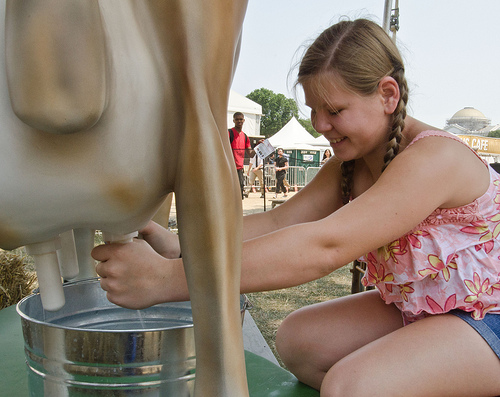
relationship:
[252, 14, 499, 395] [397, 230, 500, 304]
girl wearing top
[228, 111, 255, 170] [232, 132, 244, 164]
man wearing shirt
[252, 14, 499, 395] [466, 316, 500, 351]
girl wearing shorts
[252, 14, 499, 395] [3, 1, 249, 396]
girl milking a cow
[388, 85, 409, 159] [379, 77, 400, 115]
braid behind ear